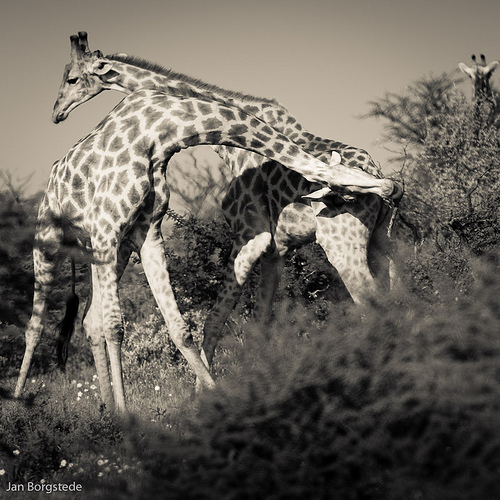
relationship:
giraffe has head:
[49, 36, 262, 176] [49, 42, 116, 115]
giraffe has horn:
[49, 36, 262, 176] [67, 25, 108, 62]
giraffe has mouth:
[49, 36, 262, 176] [47, 102, 69, 118]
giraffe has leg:
[49, 36, 262, 176] [306, 230, 406, 325]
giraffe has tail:
[49, 36, 262, 176] [374, 199, 417, 240]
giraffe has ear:
[49, 36, 262, 176] [87, 53, 135, 93]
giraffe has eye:
[49, 36, 262, 176] [62, 71, 84, 93]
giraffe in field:
[49, 36, 262, 176] [174, 390, 494, 479]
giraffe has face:
[49, 36, 262, 176] [38, 65, 126, 125]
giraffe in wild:
[49, 36, 262, 176] [7, 373, 394, 471]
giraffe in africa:
[49, 36, 262, 176] [174, 390, 494, 479]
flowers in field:
[84, 374, 106, 397] [174, 390, 494, 479]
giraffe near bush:
[49, 36, 262, 176] [273, 350, 464, 480]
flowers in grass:
[84, 374, 106, 397] [140, 425, 222, 474]